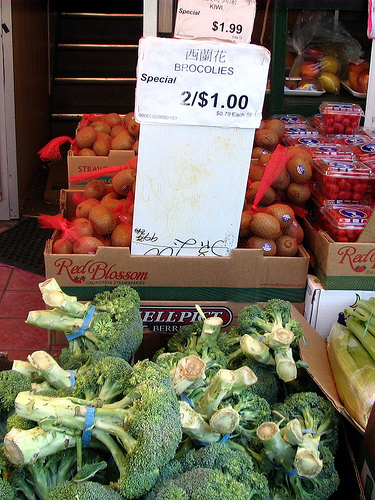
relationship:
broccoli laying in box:
[28, 284, 135, 351] [326, 420, 360, 498]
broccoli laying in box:
[15, 363, 183, 489] [326, 420, 360, 498]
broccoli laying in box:
[238, 297, 298, 377] [326, 420, 360, 498]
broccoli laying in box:
[175, 440, 267, 496] [326, 420, 360, 498]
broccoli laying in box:
[168, 314, 232, 361] [326, 420, 360, 498]